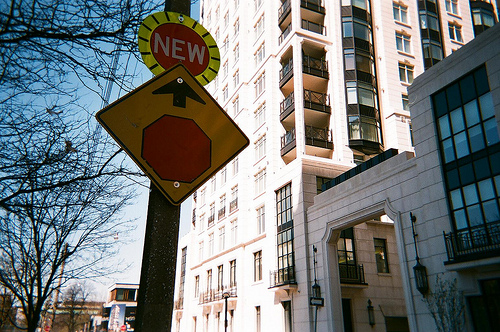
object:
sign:
[137, 10, 222, 86]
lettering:
[153, 32, 169, 56]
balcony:
[278, 87, 331, 121]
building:
[407, 21, 499, 331]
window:
[437, 112, 452, 141]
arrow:
[150, 76, 207, 108]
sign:
[96, 61, 251, 205]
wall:
[335, 222, 411, 331]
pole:
[135, 0, 191, 331]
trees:
[0, 0, 198, 331]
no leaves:
[1, 0, 205, 331]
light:
[412, 262, 430, 295]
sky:
[0, 0, 200, 306]